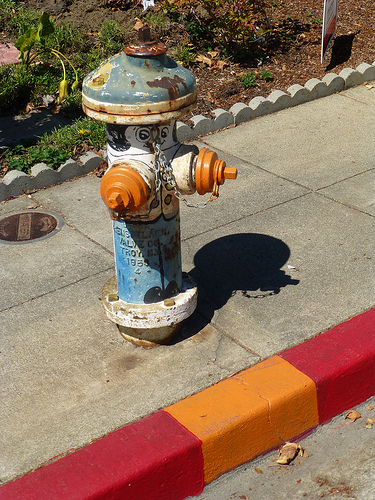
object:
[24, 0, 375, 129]
dirt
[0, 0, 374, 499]
ground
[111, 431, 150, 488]
paints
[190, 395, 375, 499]
pavement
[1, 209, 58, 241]
brown pipe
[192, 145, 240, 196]
yellow cap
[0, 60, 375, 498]
sidewalk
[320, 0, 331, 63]
sign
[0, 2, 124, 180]
grass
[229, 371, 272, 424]
crack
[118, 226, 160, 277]
engraving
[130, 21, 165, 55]
rust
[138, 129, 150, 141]
eyes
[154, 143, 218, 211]
chain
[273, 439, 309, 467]
leaf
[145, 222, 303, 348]
shadow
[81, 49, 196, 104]
cap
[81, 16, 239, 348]
fire hydrant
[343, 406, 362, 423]
leaves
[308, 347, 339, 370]
paint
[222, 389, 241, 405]
paint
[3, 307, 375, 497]
curb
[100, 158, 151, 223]
side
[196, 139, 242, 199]
side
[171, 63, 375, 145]
dividers